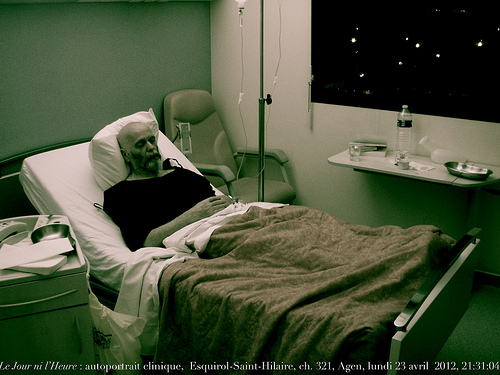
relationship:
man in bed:
[104, 122, 233, 253] [19, 127, 482, 375]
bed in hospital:
[19, 127, 482, 375] [1, 1, 499, 375]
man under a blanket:
[104, 122, 233, 253] [113, 202, 461, 375]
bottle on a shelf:
[396, 104, 411, 153] [328, 149, 499, 188]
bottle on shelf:
[396, 104, 411, 153] [328, 149, 499, 188]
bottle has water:
[396, 104, 411, 153] [396, 150, 409, 164]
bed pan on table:
[31, 223, 77, 256] [1, 215, 98, 374]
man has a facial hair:
[104, 122, 233, 253] [126, 151, 163, 178]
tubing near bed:
[235, 1, 282, 202] [19, 127, 482, 375]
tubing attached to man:
[235, 1, 282, 202] [104, 122, 233, 253]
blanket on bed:
[113, 202, 461, 375] [19, 127, 482, 375]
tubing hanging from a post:
[235, 1, 282, 202] [258, 1, 265, 202]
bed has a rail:
[19, 127, 482, 375] [393, 226, 480, 330]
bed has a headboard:
[19, 127, 482, 375] [0, 135, 94, 222]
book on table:
[6, 253, 68, 277] [1, 215, 98, 374]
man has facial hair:
[104, 122, 233, 253] [130, 147, 162, 174]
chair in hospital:
[163, 89, 295, 205] [1, 1, 499, 375]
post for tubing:
[258, 1, 265, 202] [235, 1, 282, 202]